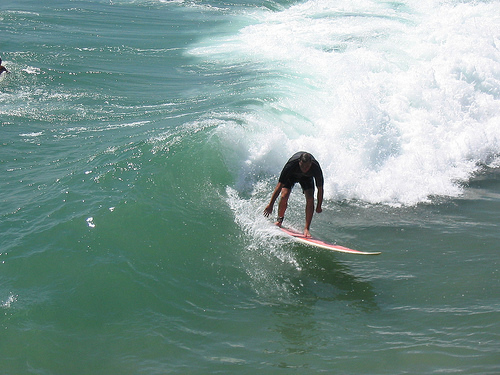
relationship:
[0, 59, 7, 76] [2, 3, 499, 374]
person in water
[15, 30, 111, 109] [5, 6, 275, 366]
ripples on watter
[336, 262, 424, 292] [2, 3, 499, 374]
ripples in water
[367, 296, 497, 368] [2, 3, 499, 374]
ripples in water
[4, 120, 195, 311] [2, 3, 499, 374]
ripples in water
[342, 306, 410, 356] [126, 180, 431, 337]
ripples in water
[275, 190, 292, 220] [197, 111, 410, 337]
leg of surfer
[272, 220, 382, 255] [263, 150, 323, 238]
board of surfer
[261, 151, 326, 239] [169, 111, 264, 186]
man riding wave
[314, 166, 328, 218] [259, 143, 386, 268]
arm of surfer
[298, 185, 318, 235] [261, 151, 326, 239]
leg of man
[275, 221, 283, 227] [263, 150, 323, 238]
foot of surfer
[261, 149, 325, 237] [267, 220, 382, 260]
man on surfboard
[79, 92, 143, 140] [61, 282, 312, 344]
ripples in water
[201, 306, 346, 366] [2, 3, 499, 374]
small ripples in water